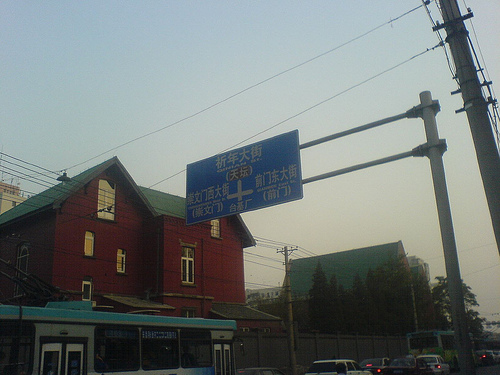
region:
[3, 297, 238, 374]
bus with a light blue roof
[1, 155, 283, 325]
red building with a green roof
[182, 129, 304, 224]
blue traffic sign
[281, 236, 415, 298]
building with green roof in the background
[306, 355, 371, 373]
a white SUV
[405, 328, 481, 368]
a blue and green bus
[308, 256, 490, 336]
row of trees behind the fence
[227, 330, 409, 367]
a long stone fence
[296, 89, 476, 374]
metal post supporting the sign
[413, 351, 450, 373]
a white hatchback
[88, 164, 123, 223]
window on large building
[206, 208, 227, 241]
window on large building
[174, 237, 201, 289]
window on large building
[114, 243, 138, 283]
window on large building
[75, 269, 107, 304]
window on large building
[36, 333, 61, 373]
window on large building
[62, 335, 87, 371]
window on large building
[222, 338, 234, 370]
window on large building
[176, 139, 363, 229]
street sign written in another language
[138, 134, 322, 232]
blue and white street sign mounted on metal pole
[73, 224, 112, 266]
window on side of red building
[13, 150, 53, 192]
electrical wires near house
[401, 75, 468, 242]
silver metal pole with sign on it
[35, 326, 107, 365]
white double doors on building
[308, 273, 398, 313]
dark green evergreens in distance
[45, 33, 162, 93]
light blue patch of sky on left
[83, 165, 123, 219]
small windows on house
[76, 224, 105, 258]
small windows on house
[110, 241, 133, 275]
small windows on house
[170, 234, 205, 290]
small windows on house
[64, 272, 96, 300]
small windows on house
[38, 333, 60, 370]
small windows on house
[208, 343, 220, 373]
small windows on house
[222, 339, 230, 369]
small windows on house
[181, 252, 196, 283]
window on the building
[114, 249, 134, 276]
window on the building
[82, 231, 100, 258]
window on the building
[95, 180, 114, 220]
window on the building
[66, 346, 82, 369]
window on the building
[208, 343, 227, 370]
window on the building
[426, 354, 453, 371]
car on the road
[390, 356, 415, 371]
car on the road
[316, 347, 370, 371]
car on the road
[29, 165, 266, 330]
The building is red.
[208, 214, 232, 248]
small window on top of store.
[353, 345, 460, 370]
Cars on the road.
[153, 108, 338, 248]
a blue street sing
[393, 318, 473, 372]
a yellow and white bus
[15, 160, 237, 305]
a large red house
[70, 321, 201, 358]
a blue sing on a bus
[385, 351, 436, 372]
a red car driving down the street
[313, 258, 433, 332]
trees next to the street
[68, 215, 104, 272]
a small window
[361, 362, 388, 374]
red light on the back of a car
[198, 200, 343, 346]
a power line pole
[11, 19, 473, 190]
a blue sky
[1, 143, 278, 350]
a brown and green house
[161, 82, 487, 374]
a street sign pole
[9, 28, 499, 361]
a scene outside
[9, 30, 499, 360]
a scene during the day time